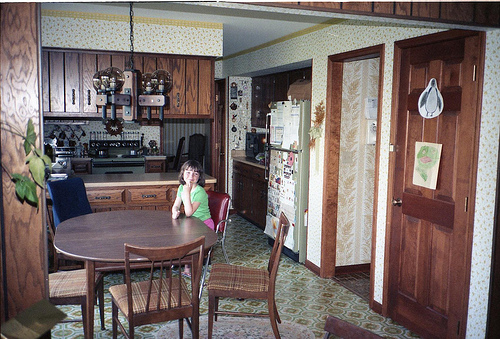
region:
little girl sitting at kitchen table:
[169, 158, 224, 238]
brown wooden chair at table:
[109, 239, 219, 337]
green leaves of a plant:
[10, 119, 60, 223]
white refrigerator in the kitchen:
[262, 89, 317, 267]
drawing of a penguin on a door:
[416, 72, 450, 122]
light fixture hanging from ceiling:
[79, 57, 178, 137]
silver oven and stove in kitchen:
[87, 137, 149, 177]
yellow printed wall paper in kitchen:
[138, 18, 220, 53]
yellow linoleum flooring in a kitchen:
[289, 278, 346, 315]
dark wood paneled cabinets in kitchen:
[40, 55, 100, 114]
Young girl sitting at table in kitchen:
[168, 160, 214, 230]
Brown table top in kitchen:
[48, 201, 214, 257]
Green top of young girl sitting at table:
[172, 183, 209, 218]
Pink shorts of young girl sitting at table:
[195, 212, 220, 232]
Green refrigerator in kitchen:
[261, 98, 309, 256]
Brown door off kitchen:
[380, 26, 480, 334]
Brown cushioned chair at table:
[203, 206, 289, 336]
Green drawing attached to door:
[406, 136, 442, 191]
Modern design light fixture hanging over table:
[85, 0, 176, 135]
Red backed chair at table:
[201, 187, 231, 292]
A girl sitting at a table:
[160, 151, 229, 232]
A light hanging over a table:
[90, 53, 175, 130]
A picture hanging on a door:
[405, 132, 446, 195]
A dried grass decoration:
[293, 94, 330, 158]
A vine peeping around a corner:
[5, 118, 68, 223]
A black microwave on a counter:
[240, 127, 269, 166]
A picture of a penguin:
[412, 74, 447, 123]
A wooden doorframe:
[320, 50, 380, 315]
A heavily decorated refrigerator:
[261, 95, 304, 252]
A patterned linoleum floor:
[280, 282, 337, 311]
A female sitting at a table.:
[160, 140, 217, 248]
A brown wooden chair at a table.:
[200, 200, 300, 337]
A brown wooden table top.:
[43, 196, 220, 282]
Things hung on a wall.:
[381, 73, 458, 204]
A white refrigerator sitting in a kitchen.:
[244, 91, 321, 287]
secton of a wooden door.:
[399, 264, 463, 276]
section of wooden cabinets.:
[29, 79, 169, 126]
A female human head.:
[175, 159, 206, 193]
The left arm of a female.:
[180, 193, 207, 219]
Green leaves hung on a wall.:
[21, 125, 69, 219]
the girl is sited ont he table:
[152, 161, 234, 234]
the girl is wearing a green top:
[166, 154, 221, 241]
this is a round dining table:
[53, 210, 225, 270]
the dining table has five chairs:
[43, 160, 305, 337]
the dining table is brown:
[51, 198, 215, 331]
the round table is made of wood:
[55, 207, 215, 337]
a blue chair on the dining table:
[38, 174, 113, 249]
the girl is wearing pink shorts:
[178, 206, 216, 253]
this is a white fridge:
[263, 93, 312, 258]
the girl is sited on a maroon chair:
[169, 162, 229, 245]